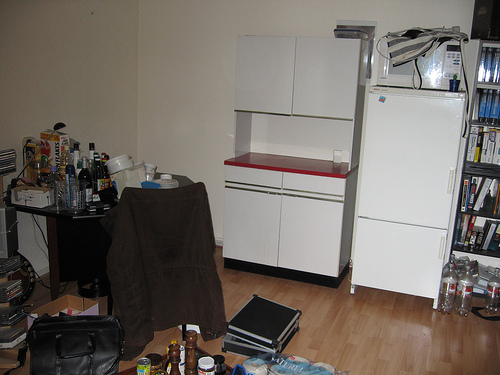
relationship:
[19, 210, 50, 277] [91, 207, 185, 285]
cords under table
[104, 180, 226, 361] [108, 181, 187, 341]
jacket on chair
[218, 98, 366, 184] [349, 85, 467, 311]
shelf beside fridge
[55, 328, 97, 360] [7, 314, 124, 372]
handle on bag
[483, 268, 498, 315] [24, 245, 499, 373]
bottle on floor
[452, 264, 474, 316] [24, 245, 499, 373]
bottle on floor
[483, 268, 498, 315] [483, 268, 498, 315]
bottle on bottle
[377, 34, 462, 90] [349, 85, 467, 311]
microwave on fridge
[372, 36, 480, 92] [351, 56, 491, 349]
microwave on top of fridge